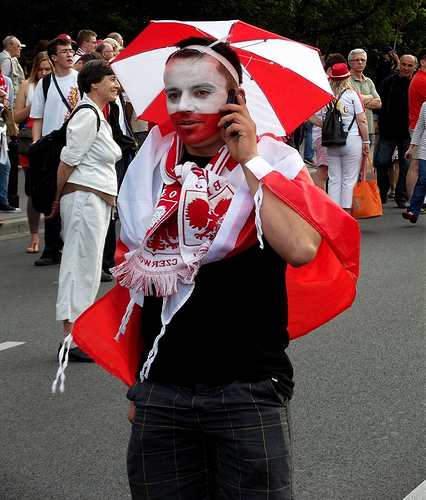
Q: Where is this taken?
A: Parade.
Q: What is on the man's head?
A: Umbrella.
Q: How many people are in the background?
A: Fifty.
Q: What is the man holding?
A: Phone.